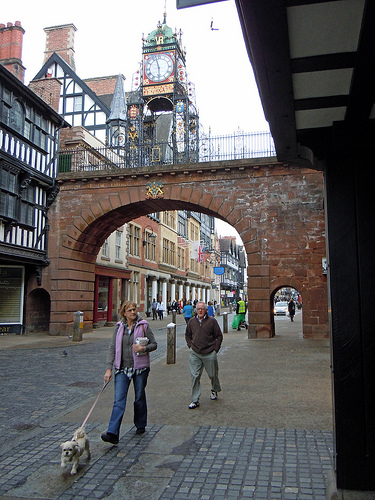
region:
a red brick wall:
[48, 171, 329, 338]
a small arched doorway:
[264, 278, 310, 336]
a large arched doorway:
[62, 190, 256, 337]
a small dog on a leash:
[56, 421, 93, 473]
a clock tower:
[138, 8, 183, 106]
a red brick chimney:
[1, 22, 24, 69]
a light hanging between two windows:
[141, 223, 159, 250]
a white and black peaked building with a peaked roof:
[25, 49, 117, 143]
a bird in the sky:
[207, 15, 219, 33]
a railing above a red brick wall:
[54, 123, 278, 175]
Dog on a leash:
[34, 352, 144, 488]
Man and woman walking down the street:
[67, 283, 291, 486]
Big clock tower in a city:
[91, 18, 217, 246]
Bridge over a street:
[38, 140, 324, 373]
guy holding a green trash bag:
[217, 288, 256, 343]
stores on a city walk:
[97, 266, 227, 322]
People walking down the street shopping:
[139, 296, 312, 344]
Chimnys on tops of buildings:
[1, 18, 111, 114]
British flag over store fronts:
[188, 239, 210, 267]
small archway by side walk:
[244, 257, 324, 353]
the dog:
[48, 380, 120, 495]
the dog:
[68, 426, 119, 486]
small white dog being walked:
[50, 426, 98, 474]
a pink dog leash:
[73, 385, 107, 426]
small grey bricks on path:
[192, 433, 307, 496]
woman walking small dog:
[56, 299, 166, 477]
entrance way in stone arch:
[254, 271, 319, 337]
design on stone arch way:
[139, 176, 173, 203]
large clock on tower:
[141, 53, 174, 85]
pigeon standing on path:
[50, 346, 77, 361]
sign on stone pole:
[77, 314, 85, 330]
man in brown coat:
[182, 295, 229, 413]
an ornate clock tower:
[127, 8, 201, 172]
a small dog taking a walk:
[59, 428, 92, 475]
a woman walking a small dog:
[58, 298, 158, 473]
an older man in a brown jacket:
[184, 301, 222, 410]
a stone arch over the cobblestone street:
[49, 123, 330, 339]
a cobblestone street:
[3, 308, 252, 454]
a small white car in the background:
[273, 299, 288, 315]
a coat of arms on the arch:
[144, 178, 165, 200]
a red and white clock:
[143, 47, 177, 88]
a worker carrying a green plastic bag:
[232, 296, 248, 332]